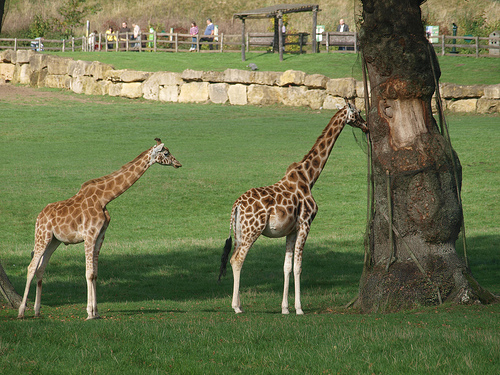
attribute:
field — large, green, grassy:
[9, 93, 369, 371]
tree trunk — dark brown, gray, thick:
[328, 2, 497, 314]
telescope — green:
[446, 15, 481, 50]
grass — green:
[44, 46, 494, 87]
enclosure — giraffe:
[5, 38, 479, 334]